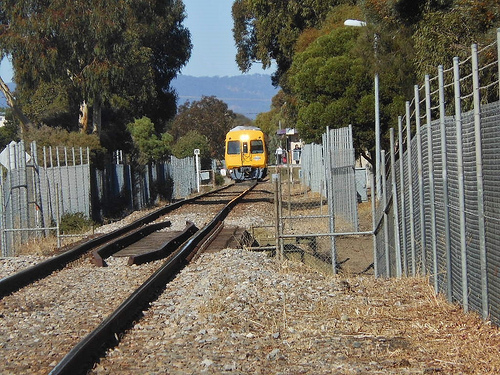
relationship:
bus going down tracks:
[217, 119, 270, 183] [0, 176, 251, 374]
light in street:
[339, 14, 389, 276] [3, 176, 496, 374]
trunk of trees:
[73, 94, 106, 153] [0, 1, 197, 143]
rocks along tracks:
[3, 202, 387, 372] [0, 176, 251, 374]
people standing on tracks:
[274, 141, 304, 164] [0, 176, 251, 374]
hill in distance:
[174, 73, 277, 126] [167, 68, 283, 90]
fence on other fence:
[0, 141, 207, 197] [0, 141, 207, 197]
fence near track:
[298, 42, 499, 320] [0, 176, 251, 374]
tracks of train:
[0, 176, 251, 374] [217, 119, 270, 183]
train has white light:
[217, 119, 270, 183] [236, 130, 256, 144]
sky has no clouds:
[178, 1, 277, 74] [191, 1, 234, 80]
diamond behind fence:
[3, 138, 33, 173] [0, 141, 207, 197]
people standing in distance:
[274, 141, 304, 164] [257, 108, 328, 164]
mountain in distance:
[174, 73, 277, 126] [167, 68, 283, 90]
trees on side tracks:
[230, 0, 495, 120] [0, 176, 251, 374]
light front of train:
[238, 132, 251, 144] [217, 119, 270, 183]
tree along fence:
[0, 1, 197, 143] [0, 141, 207, 197]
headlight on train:
[236, 130, 256, 144] [217, 119, 270, 183]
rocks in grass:
[190, 244, 420, 370] [348, 276, 500, 374]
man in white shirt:
[273, 143, 285, 164] [274, 146, 285, 155]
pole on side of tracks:
[339, 14, 389, 276] [3, 181, 269, 368]